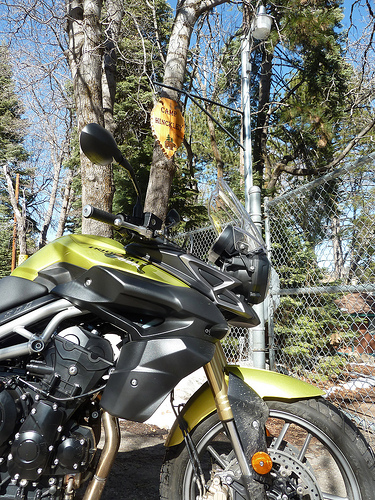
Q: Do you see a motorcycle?
A: Yes, there is a motorcycle.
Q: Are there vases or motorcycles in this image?
A: Yes, there is a motorcycle.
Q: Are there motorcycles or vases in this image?
A: Yes, there is a motorcycle.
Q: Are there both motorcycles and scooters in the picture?
A: No, there is a motorcycle but no scooters.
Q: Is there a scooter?
A: No, there are no scooters.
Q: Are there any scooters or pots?
A: No, there are no scooters or pots.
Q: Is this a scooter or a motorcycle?
A: This is a motorcycle.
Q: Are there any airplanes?
A: No, there are no airplanes.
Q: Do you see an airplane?
A: No, there are no airplanes.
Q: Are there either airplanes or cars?
A: No, there are no airplanes or cars.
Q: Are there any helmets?
A: No, there are no helmets.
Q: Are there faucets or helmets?
A: No, there are no helmets or faucets.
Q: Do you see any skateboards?
A: No, there are no skateboards.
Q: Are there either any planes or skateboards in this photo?
A: No, there are no skateboards or planes.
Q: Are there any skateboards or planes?
A: No, there are no skateboards or planes.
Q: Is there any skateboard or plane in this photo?
A: No, there are no skateboards or airplanes.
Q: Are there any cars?
A: No, there are no cars.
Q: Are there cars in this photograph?
A: No, there are no cars.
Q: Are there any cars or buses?
A: No, there are no cars or buses.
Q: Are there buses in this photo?
A: No, there are no buses.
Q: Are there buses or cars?
A: No, there are no buses or cars.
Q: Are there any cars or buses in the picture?
A: No, there are no buses or cars.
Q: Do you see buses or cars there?
A: No, there are no buses or cars.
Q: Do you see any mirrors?
A: Yes, there is a mirror.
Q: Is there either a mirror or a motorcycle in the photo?
A: Yes, there is a mirror.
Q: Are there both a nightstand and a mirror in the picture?
A: No, there is a mirror but no nightstands.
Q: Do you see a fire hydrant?
A: No, there are no fire hydrants.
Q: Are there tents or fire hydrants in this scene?
A: No, there are no fire hydrants or tents.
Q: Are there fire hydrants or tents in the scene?
A: No, there are no fire hydrants or tents.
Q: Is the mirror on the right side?
A: No, the mirror is on the left of the image.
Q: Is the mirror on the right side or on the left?
A: The mirror is on the left of the image.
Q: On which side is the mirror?
A: The mirror is on the left of the image.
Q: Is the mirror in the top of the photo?
A: Yes, the mirror is in the top of the image.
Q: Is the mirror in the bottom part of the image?
A: No, the mirror is in the top of the image.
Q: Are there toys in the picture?
A: No, there are no toys.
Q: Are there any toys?
A: No, there are no toys.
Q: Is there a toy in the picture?
A: No, there are no toys.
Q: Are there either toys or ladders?
A: No, there are no toys or ladders.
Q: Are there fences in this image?
A: Yes, there is a fence.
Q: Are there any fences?
A: Yes, there is a fence.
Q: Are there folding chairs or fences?
A: Yes, there is a fence.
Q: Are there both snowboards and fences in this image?
A: No, there is a fence but no snowboards.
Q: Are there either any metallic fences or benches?
A: Yes, there is a metal fence.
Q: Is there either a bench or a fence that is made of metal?
A: Yes, the fence is made of metal.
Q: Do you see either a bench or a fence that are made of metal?
A: Yes, the fence is made of metal.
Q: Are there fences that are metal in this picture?
A: Yes, there is a metal fence.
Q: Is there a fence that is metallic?
A: Yes, there is a fence that is metallic.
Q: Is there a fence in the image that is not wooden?
A: Yes, there is a metallic fence.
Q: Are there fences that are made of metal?
A: Yes, there is a fence that is made of metal.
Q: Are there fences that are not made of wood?
A: Yes, there is a fence that is made of metal.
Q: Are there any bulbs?
A: No, there are no bulbs.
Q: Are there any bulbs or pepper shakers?
A: No, there are no bulbs or pepper shakers.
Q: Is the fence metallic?
A: Yes, the fence is metallic.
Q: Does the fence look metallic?
A: Yes, the fence is metallic.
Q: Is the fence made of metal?
A: Yes, the fence is made of metal.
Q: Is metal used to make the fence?
A: Yes, the fence is made of metal.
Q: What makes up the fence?
A: The fence is made of metal.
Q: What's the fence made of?
A: The fence is made of metal.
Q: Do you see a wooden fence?
A: No, there is a fence but it is metallic.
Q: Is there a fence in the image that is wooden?
A: No, there is a fence but it is metallic.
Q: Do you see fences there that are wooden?
A: No, there is a fence but it is metallic.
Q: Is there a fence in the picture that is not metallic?
A: No, there is a fence but it is metallic.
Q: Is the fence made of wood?
A: No, the fence is made of metal.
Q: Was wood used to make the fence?
A: No, the fence is made of metal.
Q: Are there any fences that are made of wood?
A: No, there is a fence but it is made of metal.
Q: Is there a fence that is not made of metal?
A: No, there is a fence but it is made of metal.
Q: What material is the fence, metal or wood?
A: The fence is made of metal.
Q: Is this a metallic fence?
A: Yes, this is a metallic fence.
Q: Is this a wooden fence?
A: No, this is a metallic fence.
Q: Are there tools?
A: No, there are no tools.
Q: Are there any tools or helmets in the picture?
A: No, there are no tools or helmets.